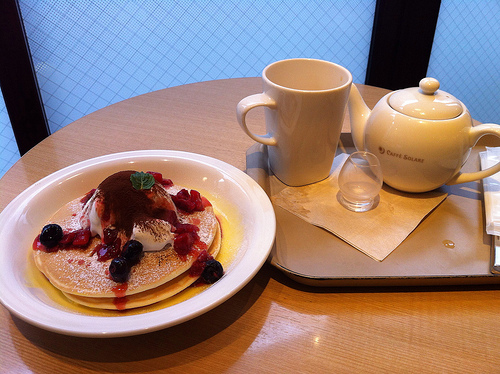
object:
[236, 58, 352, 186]
cup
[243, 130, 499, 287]
tray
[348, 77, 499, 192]
teapot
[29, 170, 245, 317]
food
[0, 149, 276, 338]
bowl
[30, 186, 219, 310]
pancake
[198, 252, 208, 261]
fruit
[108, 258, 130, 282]
fruit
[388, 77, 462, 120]
top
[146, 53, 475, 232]
items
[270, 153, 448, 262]
napkin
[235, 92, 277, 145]
handle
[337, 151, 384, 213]
glass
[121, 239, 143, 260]
fruit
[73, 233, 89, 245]
fruit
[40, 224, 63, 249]
fruit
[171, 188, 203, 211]
fruit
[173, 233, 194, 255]
fruit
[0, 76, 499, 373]
table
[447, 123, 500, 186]
handle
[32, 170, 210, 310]
syrup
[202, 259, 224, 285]
fruit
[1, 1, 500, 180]
screen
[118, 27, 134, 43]
rhombus design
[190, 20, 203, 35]
rhombus design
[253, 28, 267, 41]
rhombus design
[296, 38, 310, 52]
rhombus design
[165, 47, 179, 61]
rhombus design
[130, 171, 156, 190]
mint leaf